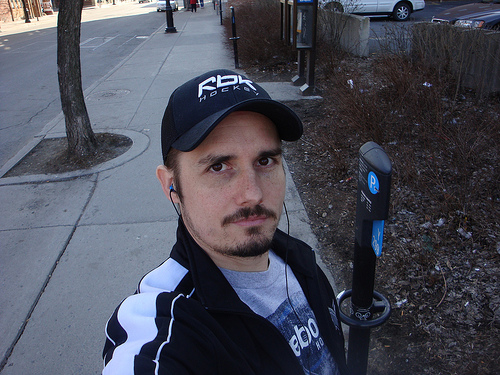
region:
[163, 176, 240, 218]
man is wearing earbuds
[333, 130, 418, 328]
the parking meter is black and blue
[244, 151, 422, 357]
man is standing next to the parking meter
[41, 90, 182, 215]
a tree in the sidewalk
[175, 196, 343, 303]
man has a beard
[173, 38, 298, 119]
man is wearing a ball cap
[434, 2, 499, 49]
vehicles parked in a lot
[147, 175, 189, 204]
earbud is blue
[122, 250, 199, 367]
a white stripe on his jacket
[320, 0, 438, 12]
the vehicle is white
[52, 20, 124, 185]
Tree growing from sidewalk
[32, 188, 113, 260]
Seams in concrete sidewalk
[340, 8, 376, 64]
Concrete divider fence for parking lot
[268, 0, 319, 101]
Payphones on concrete foundation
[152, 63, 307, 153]
Ball cap worn by young male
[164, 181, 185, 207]
Earbud for personal music system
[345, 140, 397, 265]
Meter for parking on the street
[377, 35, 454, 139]
Shrubs in the wintertime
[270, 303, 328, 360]
Reebok logo on T-shirt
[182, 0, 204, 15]
Pedestrian walking in the background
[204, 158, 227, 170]
a brown eye of a man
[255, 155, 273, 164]
a brown eye of a man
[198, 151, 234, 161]
a brown eyebrow of a man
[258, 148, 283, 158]
a brown eyebrow of a man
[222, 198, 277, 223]
a brown mustache of a man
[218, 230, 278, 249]
a brown goatee of a man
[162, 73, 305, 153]
a black and white baseball cap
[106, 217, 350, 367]
a black and white jacket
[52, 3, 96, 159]
a tree trunk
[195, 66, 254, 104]
white lettering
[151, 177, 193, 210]
blue and black ear buds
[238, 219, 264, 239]
tiny ear under man's lip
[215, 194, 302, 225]
not too neat mustache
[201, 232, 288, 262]
man with small black beard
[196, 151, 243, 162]
man's bushy black eye brows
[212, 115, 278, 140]
tiny wrinkles on man's face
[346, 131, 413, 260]
large pole beside man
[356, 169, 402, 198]
tiny blue circle on object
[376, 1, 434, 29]
black wheel with hubcap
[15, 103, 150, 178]
black tree in enclosure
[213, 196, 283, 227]
black haired neatly trimmed mustache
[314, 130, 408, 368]
large black and blue ski pole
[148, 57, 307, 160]
worn black baseball cap with logo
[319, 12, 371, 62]
weathered concrete wall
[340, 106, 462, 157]
dead and brown weeds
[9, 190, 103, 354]
concrete sidewalk slabs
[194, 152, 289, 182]
wide open focused eyes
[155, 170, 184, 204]
in-ear type music earbud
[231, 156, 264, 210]
standard Caucasion type nose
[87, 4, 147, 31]
sunlight and shade in the middle of the street